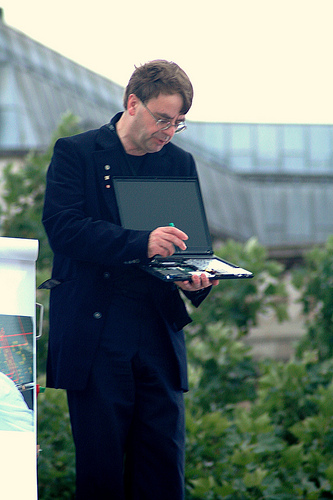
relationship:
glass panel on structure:
[230, 127, 255, 165] [5, 23, 332, 252]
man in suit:
[28, 51, 227, 498] [48, 123, 202, 496]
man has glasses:
[28, 51, 227, 498] [134, 95, 190, 136]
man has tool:
[28, 51, 227, 498] [164, 218, 189, 258]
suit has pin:
[48, 123, 202, 496] [98, 160, 114, 175]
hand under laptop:
[166, 273, 232, 295] [110, 175, 255, 283]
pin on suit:
[98, 160, 114, 175] [48, 123, 202, 496]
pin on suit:
[90, 308, 106, 322] [48, 123, 202, 496]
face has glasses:
[108, 63, 199, 161] [134, 95, 190, 136]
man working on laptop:
[28, 51, 227, 498] [110, 175, 255, 283]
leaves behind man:
[243, 238, 268, 274] [28, 51, 227, 498]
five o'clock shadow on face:
[128, 114, 172, 152] [108, 63, 199, 161]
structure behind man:
[5, 23, 332, 252] [28, 51, 227, 498]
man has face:
[28, 51, 227, 498] [108, 63, 199, 161]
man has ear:
[28, 51, 227, 498] [125, 93, 140, 120]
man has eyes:
[28, 51, 227, 498] [148, 115, 183, 127]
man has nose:
[28, 51, 227, 498] [164, 118, 177, 133]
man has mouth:
[28, 51, 227, 498] [150, 131, 170, 149]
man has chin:
[28, 51, 227, 498] [134, 132, 170, 156]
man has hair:
[28, 51, 227, 498] [118, 51, 200, 121]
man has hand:
[28, 51, 227, 498] [166, 273, 232, 295]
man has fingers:
[28, 51, 227, 498] [162, 228, 188, 257]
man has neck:
[28, 51, 227, 498] [109, 117, 166, 159]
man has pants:
[28, 51, 227, 498] [58, 293, 195, 497]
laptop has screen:
[110, 175, 255, 283] [115, 184, 211, 253]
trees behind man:
[2, 113, 332, 494] [28, 51, 227, 498]